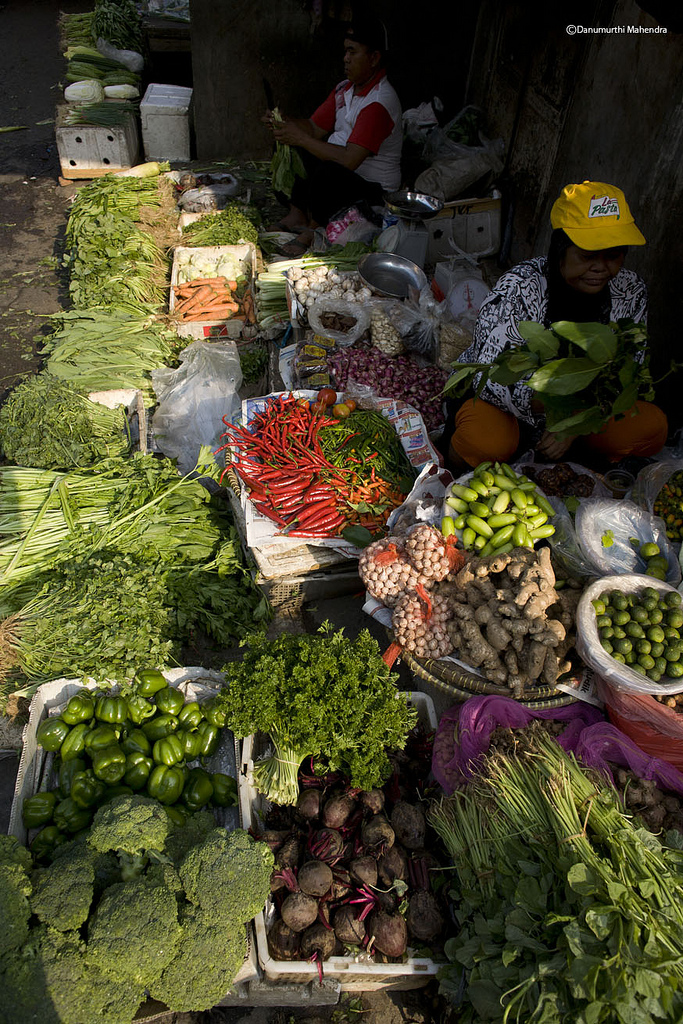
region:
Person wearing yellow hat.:
[554, 177, 664, 274]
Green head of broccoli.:
[178, 834, 272, 915]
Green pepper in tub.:
[153, 767, 185, 806]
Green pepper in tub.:
[100, 693, 130, 725]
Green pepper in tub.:
[23, 789, 58, 824]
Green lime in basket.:
[612, 604, 632, 633]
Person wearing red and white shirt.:
[314, 80, 402, 194]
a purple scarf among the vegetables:
[434, 691, 681, 810]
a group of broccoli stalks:
[35, 809, 276, 1022]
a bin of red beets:
[270, 762, 438, 957]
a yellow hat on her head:
[543, 173, 647, 254]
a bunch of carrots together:
[154, 269, 256, 326]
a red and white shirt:
[302, 78, 410, 188]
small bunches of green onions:
[60, 91, 134, 133]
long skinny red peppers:
[224, 394, 355, 540]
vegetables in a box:
[25, 945, 137, 1017]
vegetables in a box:
[175, 933, 241, 1018]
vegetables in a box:
[36, 787, 87, 846]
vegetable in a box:
[97, 700, 149, 742]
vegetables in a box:
[149, 767, 230, 804]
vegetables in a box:
[304, 785, 402, 856]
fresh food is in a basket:
[236, 395, 347, 541]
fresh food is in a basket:
[218, 631, 408, 807]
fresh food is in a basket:
[249, 761, 449, 962]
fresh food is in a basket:
[26, 661, 239, 831]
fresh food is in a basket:
[182, 827, 273, 924]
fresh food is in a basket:
[143, 905, 249, 1010]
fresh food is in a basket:
[84, 878, 182, 985]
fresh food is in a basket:
[31, 852, 94, 936]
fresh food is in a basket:
[6, 927, 144, 1022]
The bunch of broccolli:
[0, 799, 285, 1015]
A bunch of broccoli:
[11, 809, 262, 1022]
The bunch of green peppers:
[6, 668, 254, 847]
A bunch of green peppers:
[11, 671, 239, 826]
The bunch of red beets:
[251, 770, 469, 989]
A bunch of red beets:
[255, 779, 461, 968]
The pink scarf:
[429, 681, 668, 816]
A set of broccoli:
[7, 807, 300, 1021]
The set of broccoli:
[4, 786, 316, 1011]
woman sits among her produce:
[264, 18, 407, 256]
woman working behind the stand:
[446, 177, 672, 479]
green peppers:
[21, 670, 234, 841]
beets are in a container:
[260, 794, 445, 960]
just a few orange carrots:
[172, 277, 244, 323]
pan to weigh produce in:
[357, 249, 430, 301]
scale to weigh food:
[372, 187, 443, 273]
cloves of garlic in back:
[289, 261, 369, 308]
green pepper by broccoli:
[147, 763, 189, 808]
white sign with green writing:
[587, 194, 627, 223]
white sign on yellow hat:
[586, 194, 624, 224]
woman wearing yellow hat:
[463, 176, 664, 444]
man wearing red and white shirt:
[265, 11, 416, 243]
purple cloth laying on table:
[433, 691, 678, 822]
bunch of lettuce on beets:
[213, 624, 427, 814]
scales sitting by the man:
[363, 184, 443, 262]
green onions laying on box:
[54, 96, 142, 136]